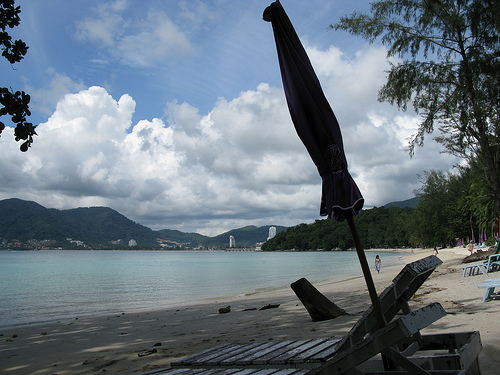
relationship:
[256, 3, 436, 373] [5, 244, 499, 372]
umbrella on beach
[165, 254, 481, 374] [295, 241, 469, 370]
chair on beach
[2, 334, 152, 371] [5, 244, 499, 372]
sand on beach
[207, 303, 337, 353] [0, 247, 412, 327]
sand near water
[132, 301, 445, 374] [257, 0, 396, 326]
chair near umbrella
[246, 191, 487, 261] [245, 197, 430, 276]
trees on mountain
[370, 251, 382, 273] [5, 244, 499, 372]
people on beach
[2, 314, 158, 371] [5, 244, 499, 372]
sand on beach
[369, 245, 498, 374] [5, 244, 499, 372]
sand on beach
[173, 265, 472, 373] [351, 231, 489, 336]
chair on beach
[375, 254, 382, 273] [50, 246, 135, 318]
people walking near water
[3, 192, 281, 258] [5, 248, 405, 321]
mountain surrounding ocean